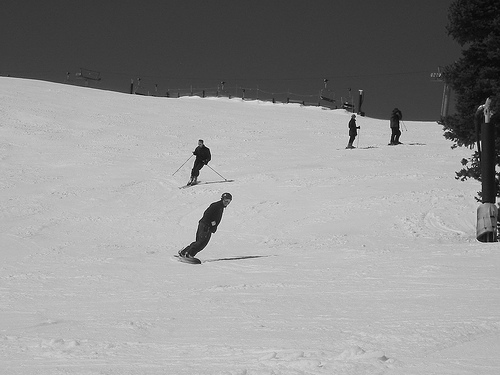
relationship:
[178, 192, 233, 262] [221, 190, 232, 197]
snowboarder wears helmet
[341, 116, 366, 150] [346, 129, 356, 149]
skier has poles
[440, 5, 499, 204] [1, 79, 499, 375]
tree on hill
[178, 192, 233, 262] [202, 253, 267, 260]
snowboarder has shadow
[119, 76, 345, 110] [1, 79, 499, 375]
fence atop hill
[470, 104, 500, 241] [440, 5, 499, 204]
cover on tree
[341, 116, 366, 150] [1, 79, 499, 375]
skier atop hill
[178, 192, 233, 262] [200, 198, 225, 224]
snowboarder has coat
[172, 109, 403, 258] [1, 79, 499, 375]
people on hill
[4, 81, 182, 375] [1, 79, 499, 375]
snow on ground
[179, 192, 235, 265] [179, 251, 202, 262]
man on snowboard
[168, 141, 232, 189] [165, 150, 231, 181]
man on skis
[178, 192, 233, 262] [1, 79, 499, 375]
snowboarder going down hill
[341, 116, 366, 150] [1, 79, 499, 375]
skier going down hill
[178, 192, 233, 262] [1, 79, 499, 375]
snowboarder on hill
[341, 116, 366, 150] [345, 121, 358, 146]
skier wears ski suit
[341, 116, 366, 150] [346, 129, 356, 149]
skier holds poles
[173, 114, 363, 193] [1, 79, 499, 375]
skiers on hill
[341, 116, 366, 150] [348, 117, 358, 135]
skier wears jacket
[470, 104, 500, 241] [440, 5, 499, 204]
pipe around tree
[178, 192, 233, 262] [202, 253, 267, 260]
snowboarder casts shadow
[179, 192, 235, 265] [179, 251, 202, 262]
man rides snowboard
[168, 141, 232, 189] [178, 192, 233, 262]
man behind snowboarder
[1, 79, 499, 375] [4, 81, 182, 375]
hill covered in snow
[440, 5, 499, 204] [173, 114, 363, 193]
tree near skiers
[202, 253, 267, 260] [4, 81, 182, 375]
shadow in snow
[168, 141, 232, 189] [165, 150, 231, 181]
skier holds poles